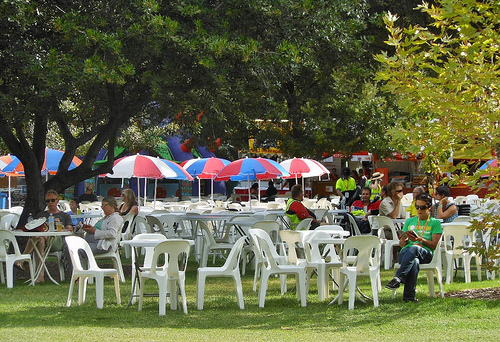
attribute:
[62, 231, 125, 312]
chairs — white, plastic, empty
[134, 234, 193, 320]
chairs — white, plastic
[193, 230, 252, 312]
chairs — white, plastic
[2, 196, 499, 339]
lawn — green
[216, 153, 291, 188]
umbrellas — raised, blue, red, open, red white blue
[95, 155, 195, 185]
umbrellas — raised, red, white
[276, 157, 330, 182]
umbrellas — raised, red, white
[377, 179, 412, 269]
people — sitting, eating, outdoors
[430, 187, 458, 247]
people — sitting, eating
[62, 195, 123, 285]
people — sitting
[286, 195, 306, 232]
vest — green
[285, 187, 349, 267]
man — sitting, worker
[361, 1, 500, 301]
tree — coverage, green, light green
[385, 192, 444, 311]
man — seated, sitting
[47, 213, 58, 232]
bottle — plastic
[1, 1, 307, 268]
tree — dark green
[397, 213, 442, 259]
shirt — green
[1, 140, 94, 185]
umbrellas — orange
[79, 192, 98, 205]
shirt — black